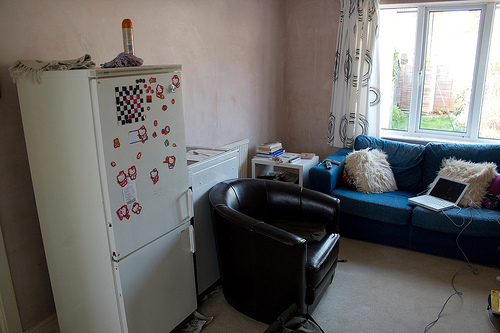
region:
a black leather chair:
[206, 177, 351, 319]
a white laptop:
[402, 156, 476, 232]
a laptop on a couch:
[386, 163, 484, 238]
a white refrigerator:
[95, 58, 189, 328]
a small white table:
[248, 138, 316, 179]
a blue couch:
[316, 131, 461, 230]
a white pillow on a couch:
[306, 139, 411, 223]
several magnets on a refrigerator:
[108, 75, 179, 221]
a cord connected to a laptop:
[452, 187, 474, 332]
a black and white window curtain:
[320, 2, 393, 155]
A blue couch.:
[314, 132, 498, 262]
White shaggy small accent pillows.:
[343, 145, 498, 205]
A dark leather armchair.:
[208, 175, 345, 330]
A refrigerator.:
[18, 60, 197, 332]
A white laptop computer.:
[406, 173, 469, 213]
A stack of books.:
[256, 138, 286, 159]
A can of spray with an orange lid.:
[119, 14, 139, 60]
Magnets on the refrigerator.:
[87, 76, 182, 220]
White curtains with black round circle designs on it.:
[323, 0, 382, 151]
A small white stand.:
[249, 148, 316, 202]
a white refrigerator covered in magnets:
[5, 54, 209, 331]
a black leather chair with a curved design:
[203, 171, 350, 320]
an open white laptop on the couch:
[405, 170, 470, 217]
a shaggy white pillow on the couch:
[345, 144, 398, 193]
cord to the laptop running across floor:
[443, 214, 480, 331]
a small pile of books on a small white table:
[250, 142, 287, 161]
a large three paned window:
[371, 3, 498, 142]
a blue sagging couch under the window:
[314, 127, 498, 245]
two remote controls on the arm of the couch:
[320, 156, 342, 171]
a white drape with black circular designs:
[325, 8, 373, 160]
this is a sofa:
[221, 189, 335, 304]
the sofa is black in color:
[218, 183, 337, 295]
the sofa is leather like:
[232, 198, 320, 259]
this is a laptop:
[411, 177, 461, 212]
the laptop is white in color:
[423, 196, 443, 210]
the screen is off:
[436, 182, 454, 195]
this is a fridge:
[61, 106, 179, 299]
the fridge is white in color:
[134, 250, 180, 293]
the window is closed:
[397, 20, 483, 102]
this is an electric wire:
[451, 246, 480, 274]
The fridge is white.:
[13, 49, 208, 330]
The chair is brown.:
[211, 173, 339, 315]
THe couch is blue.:
[310, 138, 499, 270]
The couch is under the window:
[310, 3, 497, 256]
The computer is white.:
[406, 171, 468, 220]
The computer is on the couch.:
[315, 132, 499, 242]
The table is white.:
[247, 136, 311, 188]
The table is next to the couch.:
[245, 133, 498, 248]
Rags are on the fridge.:
[5, 54, 156, 73]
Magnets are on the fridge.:
[112, 71, 194, 228]